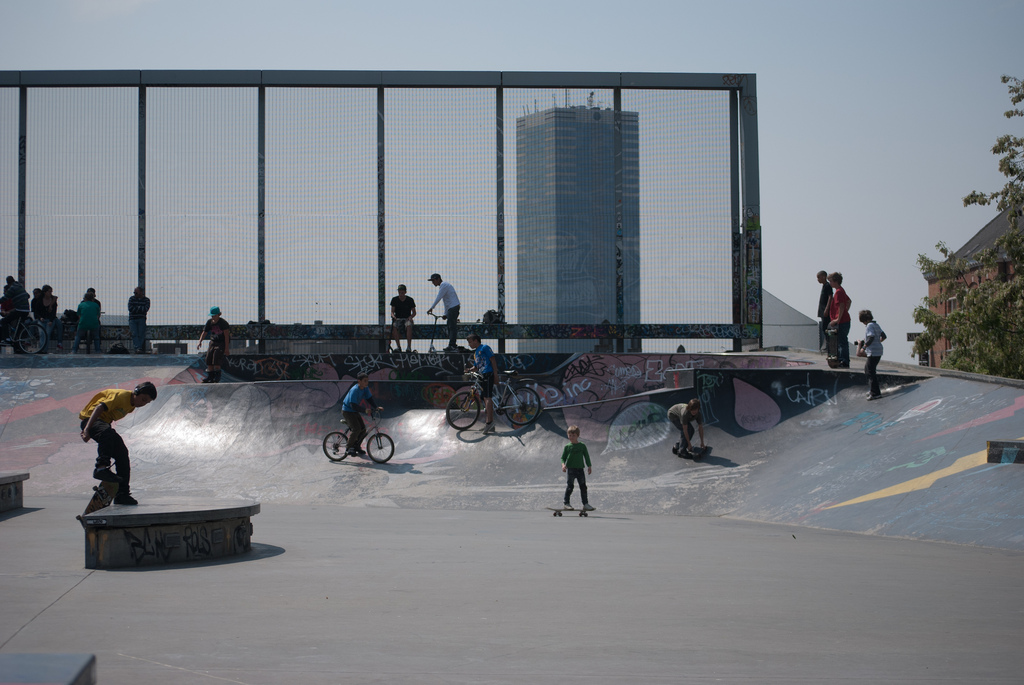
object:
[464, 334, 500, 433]
person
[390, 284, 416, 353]
person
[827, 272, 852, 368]
person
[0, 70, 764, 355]
fence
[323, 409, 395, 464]
bike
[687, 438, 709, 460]
skateboard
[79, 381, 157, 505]
person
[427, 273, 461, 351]
person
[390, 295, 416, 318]
shirt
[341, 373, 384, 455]
child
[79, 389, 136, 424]
shirt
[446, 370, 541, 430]
bike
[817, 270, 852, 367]
people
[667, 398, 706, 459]
child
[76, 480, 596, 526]
skateboarders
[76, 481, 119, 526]
skateboard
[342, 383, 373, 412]
shirt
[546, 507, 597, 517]
skateboard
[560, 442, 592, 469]
shirt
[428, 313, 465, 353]
scooter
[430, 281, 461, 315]
shirt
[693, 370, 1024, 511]
graffiti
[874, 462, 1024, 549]
ramp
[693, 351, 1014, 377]
park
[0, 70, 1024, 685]
skatepark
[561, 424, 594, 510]
boy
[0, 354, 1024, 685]
background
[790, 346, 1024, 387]
side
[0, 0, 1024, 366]
sky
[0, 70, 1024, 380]
everything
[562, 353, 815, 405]
wall